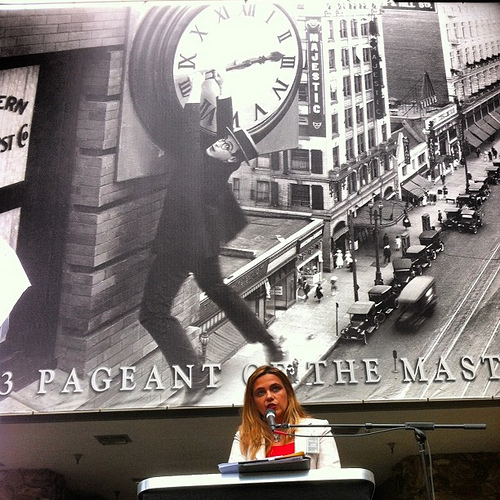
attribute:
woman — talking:
[228, 366, 342, 469]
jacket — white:
[228, 419, 342, 470]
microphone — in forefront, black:
[263, 408, 279, 433]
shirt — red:
[267, 442, 297, 457]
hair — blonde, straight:
[237, 365, 310, 460]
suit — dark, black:
[139, 98, 273, 377]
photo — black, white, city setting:
[1, 0, 500, 418]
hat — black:
[225, 123, 260, 168]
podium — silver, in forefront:
[135, 469, 377, 499]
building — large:
[384, 3, 500, 152]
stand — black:
[278, 421, 488, 499]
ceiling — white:
[0, 408, 499, 499]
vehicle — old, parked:
[341, 300, 380, 345]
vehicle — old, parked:
[370, 282, 399, 314]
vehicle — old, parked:
[391, 257, 416, 288]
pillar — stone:
[378, 453, 499, 499]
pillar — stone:
[0, 469, 66, 498]